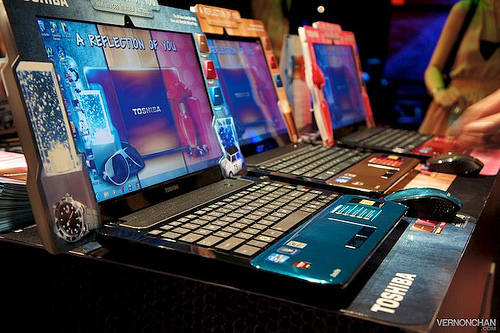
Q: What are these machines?
A: Computers.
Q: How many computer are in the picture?
A: 3.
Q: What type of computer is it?
A: Laptop.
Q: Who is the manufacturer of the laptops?
A: Toshiba.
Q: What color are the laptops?
A: Black.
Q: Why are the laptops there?
A: For Advertisement.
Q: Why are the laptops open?
A: Display the screen.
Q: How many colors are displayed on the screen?
A: 3.